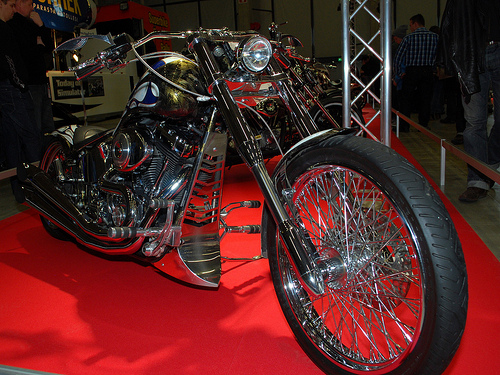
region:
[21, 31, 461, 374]
black and silver motor bike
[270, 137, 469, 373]
black tire on bike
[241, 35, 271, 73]
head light on bike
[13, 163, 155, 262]
exhaust pipe on bike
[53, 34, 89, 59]
side mirror on bike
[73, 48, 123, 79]
metal handle on bike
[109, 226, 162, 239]
metal foot stand on bike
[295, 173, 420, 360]
silver spokes in tire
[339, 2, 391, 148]
grey metal support post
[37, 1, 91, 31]
blue and yellow sign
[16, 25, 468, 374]
The motorcycle is metallic.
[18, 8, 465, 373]
The motorcycle has one headlight.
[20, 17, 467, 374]
The motorcycle is mostly grey.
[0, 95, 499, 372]
The platform is red.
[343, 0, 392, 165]
The metal beams are grey.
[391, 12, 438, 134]
The man wears a flannel shirt.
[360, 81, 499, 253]
The guard rails are metal.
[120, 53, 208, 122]
The helmet is metal.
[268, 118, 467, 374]
The tire is rubber.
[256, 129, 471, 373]
The tire is round.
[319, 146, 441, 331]
Black front tire on bike.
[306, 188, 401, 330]
Silver spokes on front tire.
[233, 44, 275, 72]
Light on front of bike.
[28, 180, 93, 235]
Silver exhaust on bike.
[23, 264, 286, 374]
Bike sitting on red surface.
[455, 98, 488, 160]
Person wearing dark pants.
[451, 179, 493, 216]
Person wearing dark shoes.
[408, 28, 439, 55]
Person wearing plaid shirt.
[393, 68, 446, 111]
Person wearing dark pants.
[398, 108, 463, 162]
Silver railing in front of bike.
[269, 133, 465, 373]
the tire is black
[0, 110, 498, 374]
the carpet is red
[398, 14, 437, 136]
someone is standing around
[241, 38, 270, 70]
headlight on the bike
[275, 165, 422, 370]
the spokes are chrome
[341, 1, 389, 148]
the pillar is metal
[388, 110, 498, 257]
the railing is metal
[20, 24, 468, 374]
a motorcycle on display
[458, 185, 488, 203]
the shoe is black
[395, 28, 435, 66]
a checker pattern shirt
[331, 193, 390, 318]
the spokes of a motorcycle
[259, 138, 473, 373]
the front wheel of a motorcycle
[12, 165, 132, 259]
the mufflers of a motorcycle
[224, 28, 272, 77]
the headlight of a motorcycle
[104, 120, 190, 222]
the engine of a motorcycle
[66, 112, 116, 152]
the seat of a motorcycle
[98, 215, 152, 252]
the foot pedal of a motorcycle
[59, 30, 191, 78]
the handle bar of a motorcycle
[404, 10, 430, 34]
the side of a man's head